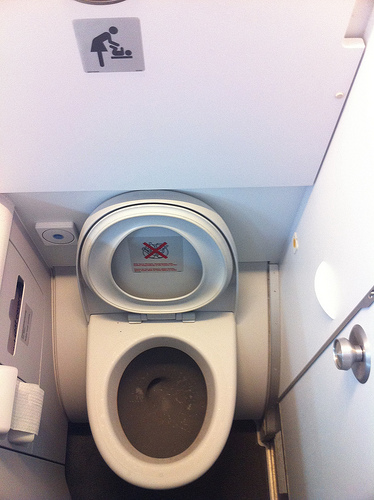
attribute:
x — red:
[141, 242, 168, 260]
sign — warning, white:
[128, 237, 185, 275]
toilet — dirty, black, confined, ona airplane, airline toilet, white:
[76, 190, 239, 489]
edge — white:
[74, 190, 242, 315]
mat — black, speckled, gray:
[65, 425, 271, 500]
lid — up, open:
[75, 190, 241, 323]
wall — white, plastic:
[0, 0, 373, 268]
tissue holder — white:
[1, 240, 42, 381]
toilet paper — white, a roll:
[14, 381, 44, 434]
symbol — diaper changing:
[72, 16, 147, 73]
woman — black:
[89, 26, 120, 66]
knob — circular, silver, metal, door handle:
[332, 324, 370, 383]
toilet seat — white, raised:
[79, 203, 232, 315]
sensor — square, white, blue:
[34, 221, 79, 249]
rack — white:
[1, 363, 44, 444]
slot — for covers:
[8, 276, 24, 356]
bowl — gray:
[117, 347, 208, 457]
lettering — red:
[132, 261, 179, 274]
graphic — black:
[91, 25, 133, 65]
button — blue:
[53, 232, 65, 241]